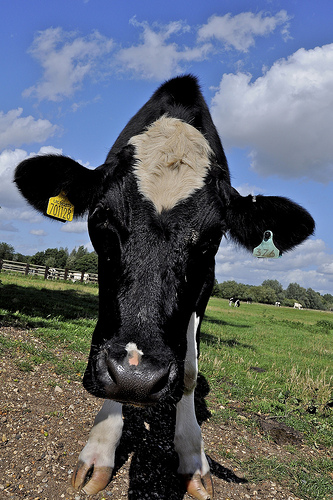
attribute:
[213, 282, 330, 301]
leaves — green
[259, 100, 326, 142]
cloud — fluffy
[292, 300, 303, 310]
white cow — white 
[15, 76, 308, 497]
cow — white, black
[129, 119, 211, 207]
spot — white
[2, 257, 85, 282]
fence — wood, picket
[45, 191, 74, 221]
tag — yellow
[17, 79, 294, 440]
cow — white, black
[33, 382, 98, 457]
dirt — rocky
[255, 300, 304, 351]
grass — green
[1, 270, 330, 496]
grass — green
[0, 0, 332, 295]
sky — blue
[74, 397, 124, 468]
leg — white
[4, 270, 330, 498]
ground — pictured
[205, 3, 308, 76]
sky — clear, blue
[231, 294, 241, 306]
cow grazing — black, white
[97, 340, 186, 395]
nose — black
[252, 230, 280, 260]
tag — white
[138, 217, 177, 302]
cow — black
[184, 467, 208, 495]
hoof — brown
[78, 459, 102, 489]
hoof — brown